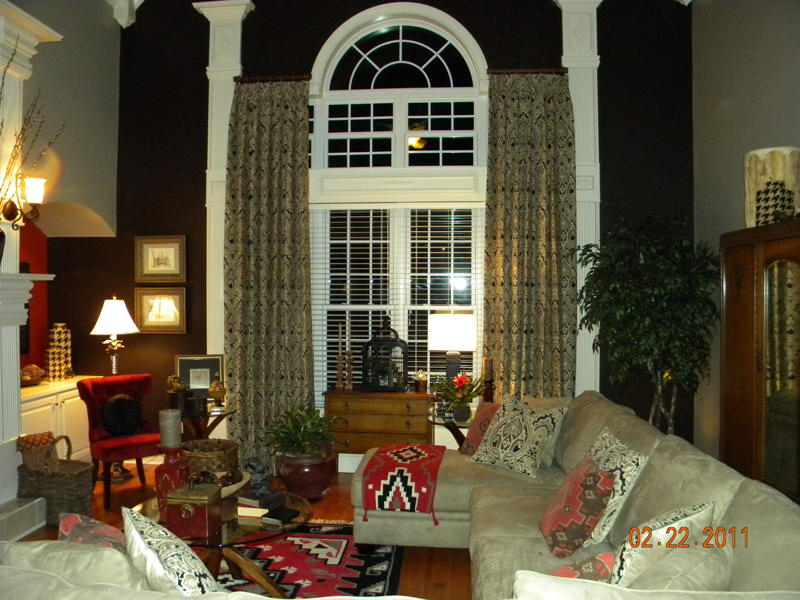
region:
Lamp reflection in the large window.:
[319, 12, 480, 389]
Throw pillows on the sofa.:
[543, 432, 716, 590]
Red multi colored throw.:
[362, 444, 443, 517]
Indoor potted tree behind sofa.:
[580, 240, 738, 437]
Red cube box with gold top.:
[159, 485, 223, 549]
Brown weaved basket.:
[20, 428, 97, 520]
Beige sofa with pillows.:
[342, 371, 793, 592]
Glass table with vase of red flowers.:
[430, 366, 484, 444]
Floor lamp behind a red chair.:
[68, 297, 167, 513]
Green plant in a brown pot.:
[269, 408, 346, 499]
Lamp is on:
[95, 288, 139, 377]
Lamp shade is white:
[87, 288, 139, 379]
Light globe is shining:
[11, 154, 53, 231]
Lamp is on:
[418, 307, 482, 403]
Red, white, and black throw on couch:
[362, 434, 448, 525]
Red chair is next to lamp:
[68, 365, 181, 480]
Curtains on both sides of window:
[229, 67, 571, 444]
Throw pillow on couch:
[468, 385, 573, 479]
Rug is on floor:
[231, 517, 405, 591]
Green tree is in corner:
[567, 236, 737, 432]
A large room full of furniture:
[54, 40, 762, 598]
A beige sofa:
[388, 379, 773, 592]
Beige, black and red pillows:
[478, 404, 680, 580]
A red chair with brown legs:
[77, 352, 162, 492]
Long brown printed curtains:
[233, 66, 572, 451]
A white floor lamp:
[87, 279, 143, 365]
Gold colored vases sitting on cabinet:
[44, 310, 82, 399]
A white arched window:
[306, 0, 487, 321]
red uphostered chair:
[77, 371, 170, 508]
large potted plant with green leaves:
[573, 222, 721, 447]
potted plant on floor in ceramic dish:
[267, 408, 339, 500]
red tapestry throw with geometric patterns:
[361, 438, 445, 530]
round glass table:
[120, 467, 317, 599]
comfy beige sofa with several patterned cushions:
[347, 387, 790, 595]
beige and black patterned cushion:
[482, 396, 554, 471]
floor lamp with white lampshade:
[90, 285, 132, 369]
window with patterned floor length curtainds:
[229, 66, 595, 504]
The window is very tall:
[291, 15, 553, 485]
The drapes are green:
[218, 53, 594, 490]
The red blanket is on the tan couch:
[326, 358, 744, 585]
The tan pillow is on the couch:
[480, 370, 728, 550]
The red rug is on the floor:
[88, 438, 467, 594]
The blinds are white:
[278, 113, 522, 413]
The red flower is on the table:
[406, 329, 551, 479]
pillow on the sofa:
[465, 395, 571, 477]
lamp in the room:
[83, 296, 134, 378]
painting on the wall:
[135, 238, 191, 294]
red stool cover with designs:
[352, 435, 462, 526]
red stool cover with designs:
[346, 431, 461, 529]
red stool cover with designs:
[357, 426, 459, 527]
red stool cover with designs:
[352, 431, 458, 531]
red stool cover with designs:
[356, 437, 447, 526]